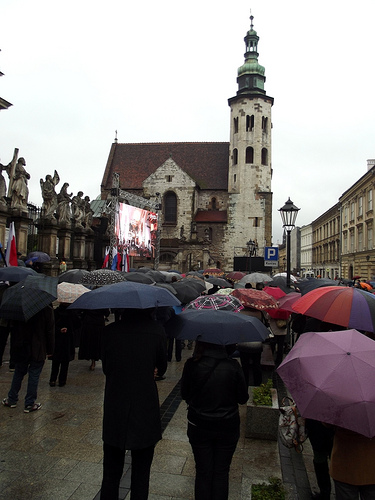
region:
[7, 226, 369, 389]
A bunch of umbrellas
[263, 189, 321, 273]
A street lamp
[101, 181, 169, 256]
A video screen of some sort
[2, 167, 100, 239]
Various types of statues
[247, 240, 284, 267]
A street sign of some kind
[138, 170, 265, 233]
A very old building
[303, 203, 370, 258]
Building in the distance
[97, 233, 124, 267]
Some kind of flags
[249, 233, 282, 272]
A blue street sign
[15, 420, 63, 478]
a wet sidewalk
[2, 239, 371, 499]
people standing on the sidewalk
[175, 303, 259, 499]
person holding a black umbrella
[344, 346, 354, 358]
black circle on the top of the umbrella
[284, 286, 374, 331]
multi-colored striped umbrella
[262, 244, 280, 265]
blue and white sign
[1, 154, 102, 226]
row of bronze statues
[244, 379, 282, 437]
planter with a green plant in it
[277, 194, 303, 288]
black light post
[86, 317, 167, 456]
long black jacket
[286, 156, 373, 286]
row of buildings along the street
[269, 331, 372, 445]
an open pink umbrella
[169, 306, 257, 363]
an open blue umbrella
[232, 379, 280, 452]
a small plant in stone planter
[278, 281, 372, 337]
a opened multi colored umbrella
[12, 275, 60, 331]
a black and green umbrella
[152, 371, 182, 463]
black tiles on street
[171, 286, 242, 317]
pink black and white umbrella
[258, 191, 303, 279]
black and white light pole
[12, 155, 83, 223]
statues at the top of a building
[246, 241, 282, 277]
blue and white parking sign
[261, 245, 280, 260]
blue sign beside street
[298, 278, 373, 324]
striped rainbow umbrella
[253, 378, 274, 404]
small green bush in stone planter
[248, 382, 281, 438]
grey stone planter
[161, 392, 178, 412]
black stone tile on ground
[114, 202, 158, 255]
large projector display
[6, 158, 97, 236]
row of statues beside street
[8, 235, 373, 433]
large group of people using umbrellas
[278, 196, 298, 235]
black metal street light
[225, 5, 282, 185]
large stone tower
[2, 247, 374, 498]
bunch of people standing on the street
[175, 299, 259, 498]
person holding an umbrella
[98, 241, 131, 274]
group of flags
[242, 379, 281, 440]
planter with a small green plant in it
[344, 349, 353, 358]
black button on top of the umbrella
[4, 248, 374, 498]
people holding umbrellas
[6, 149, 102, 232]
row of statues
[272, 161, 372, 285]
row of old buildings